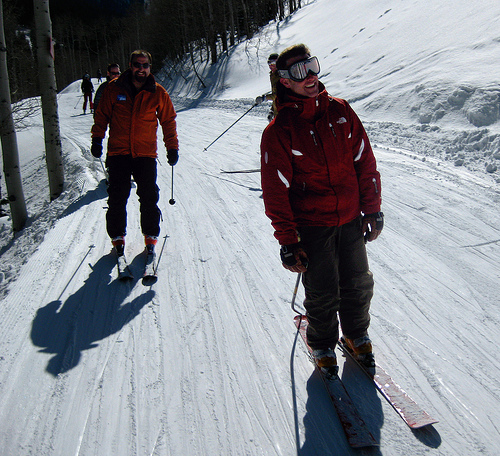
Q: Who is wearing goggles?
A: The man on the right.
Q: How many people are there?
A: Six.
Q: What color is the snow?
A: White.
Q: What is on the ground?
A: Snow.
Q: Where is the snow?
A: On the ground.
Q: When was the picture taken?
A: Daytime.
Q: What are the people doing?
A: Skiing.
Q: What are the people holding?
A: Ski poles.